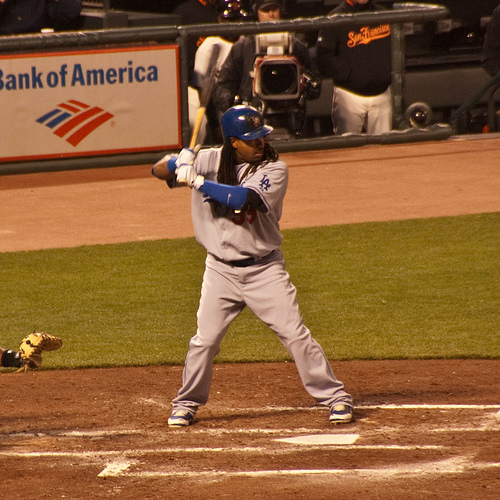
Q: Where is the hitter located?
A: Batter's box.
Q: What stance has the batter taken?
A: Ready stance.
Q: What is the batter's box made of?
A: White chalk.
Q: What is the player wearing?
A: Grey and blue uniform.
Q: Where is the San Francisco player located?
A: Dugout.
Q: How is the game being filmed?
A: By the large camera in the dugout.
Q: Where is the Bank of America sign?
A: Behind the player on the fence.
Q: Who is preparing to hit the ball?
A: A baseball player.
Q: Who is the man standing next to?
A: The cameraman.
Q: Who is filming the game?
A: A man in a black jacket.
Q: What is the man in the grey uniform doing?
A: Preparing to hit a baseball.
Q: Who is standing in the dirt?
A: The batter.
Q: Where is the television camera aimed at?
A: The baseball player.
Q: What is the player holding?
A: A baseball bat.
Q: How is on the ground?
A: Couch.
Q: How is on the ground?
A: Couch.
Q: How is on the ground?
A: Grass.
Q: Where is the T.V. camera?
A: Behind the glass.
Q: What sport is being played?
A: Baseball.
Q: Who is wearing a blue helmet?
A: The batter.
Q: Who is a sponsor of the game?
A: Bank of America.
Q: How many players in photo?
A: One.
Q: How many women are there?
A: None.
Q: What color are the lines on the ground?
A: White.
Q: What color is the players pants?
A: Gray.